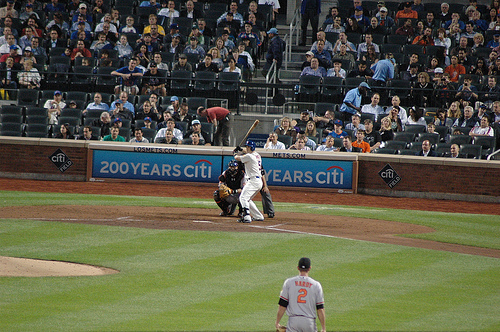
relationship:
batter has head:
[225, 133, 269, 226] [240, 138, 257, 153]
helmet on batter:
[234, 128, 256, 157] [225, 133, 269, 226]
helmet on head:
[234, 128, 256, 157] [240, 138, 257, 153]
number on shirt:
[296, 282, 308, 306] [278, 270, 326, 317]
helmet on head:
[244, 139, 257, 153] [245, 143, 259, 152]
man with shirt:
[352, 127, 373, 151] [349, 140, 369, 150]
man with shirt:
[339, 81, 371, 117] [338, 88, 363, 112]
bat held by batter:
[232, 118, 260, 156] [233, 141, 266, 223]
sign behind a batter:
[99, 149, 225, 185] [230, 143, 266, 221]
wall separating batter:
[2, 131, 479, 201] [225, 133, 269, 226]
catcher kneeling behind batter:
[214, 161, 251, 218] [232, 112, 269, 227]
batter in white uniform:
[225, 133, 269, 231] [230, 150, 265, 214]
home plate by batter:
[192, 213, 212, 224] [228, 145, 268, 228]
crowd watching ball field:
[1, 1, 491, 157] [0, 171, 499, 328]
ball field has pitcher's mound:
[0, 171, 499, 328] [1, 241, 135, 297]